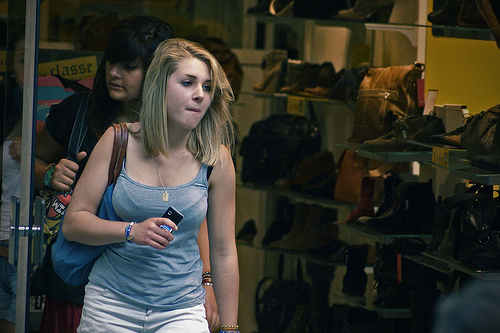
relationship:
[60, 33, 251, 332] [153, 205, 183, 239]
girl holding cell phone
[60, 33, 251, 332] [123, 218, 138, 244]
girl wearing bracelet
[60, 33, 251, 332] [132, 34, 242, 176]
girl has hair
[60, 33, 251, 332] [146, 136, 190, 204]
girl wearing necklace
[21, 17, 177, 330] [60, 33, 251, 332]
woman behind girl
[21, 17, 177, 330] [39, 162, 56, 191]
woman wearing watch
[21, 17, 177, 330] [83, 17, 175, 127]
woman has hair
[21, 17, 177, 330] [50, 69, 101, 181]
woman carrying purse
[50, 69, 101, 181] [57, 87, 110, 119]
purse on shoulder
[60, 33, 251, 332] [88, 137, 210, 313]
girl wearing tank top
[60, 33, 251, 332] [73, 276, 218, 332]
girl wearing pants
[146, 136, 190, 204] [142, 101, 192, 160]
necklace around neck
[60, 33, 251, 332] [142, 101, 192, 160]
girl has neck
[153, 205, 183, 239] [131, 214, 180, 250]
cell phone in hand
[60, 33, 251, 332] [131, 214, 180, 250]
girl has hand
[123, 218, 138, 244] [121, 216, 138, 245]
bracelet on wrist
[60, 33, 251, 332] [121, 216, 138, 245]
girl has wrist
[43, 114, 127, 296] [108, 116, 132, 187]
bag has strap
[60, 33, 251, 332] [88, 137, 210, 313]
girl has tank top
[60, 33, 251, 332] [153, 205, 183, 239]
girl holds cell phone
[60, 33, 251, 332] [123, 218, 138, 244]
girl wears bracelet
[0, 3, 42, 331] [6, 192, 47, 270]
door has handle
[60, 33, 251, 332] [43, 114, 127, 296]
girl carrying bag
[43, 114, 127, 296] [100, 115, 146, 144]
bag on shoulder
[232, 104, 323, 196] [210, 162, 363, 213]
purse on shelf